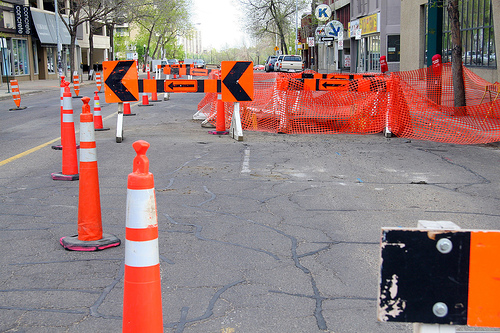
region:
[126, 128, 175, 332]
An orange and white road sign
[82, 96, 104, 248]
An orange and white road sign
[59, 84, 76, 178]
An orange and white road sign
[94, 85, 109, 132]
An orange and white road sign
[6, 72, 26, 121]
An orange and white road sign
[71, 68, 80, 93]
An orange and white road sign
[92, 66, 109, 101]
An orange and white road sign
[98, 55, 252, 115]
A orange and black direction baner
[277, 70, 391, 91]
A orange and black direction baner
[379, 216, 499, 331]
A orange and black direction baner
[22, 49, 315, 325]
Orange cones are on the ground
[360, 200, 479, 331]
A black end is on a sign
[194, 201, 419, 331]
Lines are in the street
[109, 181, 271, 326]
The cones have white stripes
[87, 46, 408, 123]
Arrows are on the signs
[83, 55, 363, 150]
Black arrows are on the signs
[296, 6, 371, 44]
The letter K is pictured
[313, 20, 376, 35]
An arrow is facing diagonal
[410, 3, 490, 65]
Windows are on the building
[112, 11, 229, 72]
Trees are in the distance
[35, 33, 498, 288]
The road is under construction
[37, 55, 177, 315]
Several orange safety cones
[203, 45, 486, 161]
Orange tarp blocking hole in the ground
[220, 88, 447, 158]
Hole in the ground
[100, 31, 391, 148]
Orange traffic detour signs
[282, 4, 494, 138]
Businesses on the side of the street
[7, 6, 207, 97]
More businesses on the left side of the street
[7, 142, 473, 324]
Cracks in the road patched by sealant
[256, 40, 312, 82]
Vehicles parked on the side of the road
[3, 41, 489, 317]
A city street under repair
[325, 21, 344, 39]
blue arrow pointing down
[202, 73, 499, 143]
orange construction fencing around hole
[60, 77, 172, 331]
orange and white caution cones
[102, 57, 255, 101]
detour arrow signs pointing left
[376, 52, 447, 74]
red bags over meters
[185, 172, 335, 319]
multiple cracks in pavement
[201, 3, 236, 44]
bright sunny sky in background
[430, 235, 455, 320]
silver bolts on barrier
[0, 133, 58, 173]
yellow stripe on road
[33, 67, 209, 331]
cones are orange and white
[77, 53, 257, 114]
black arrows on signs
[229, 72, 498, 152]
orange fencing beside signs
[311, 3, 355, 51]
the signs are white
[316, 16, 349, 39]
blue arrow on sign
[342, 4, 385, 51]
the sign is yellow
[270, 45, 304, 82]
the car is silver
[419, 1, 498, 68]
window frames are green